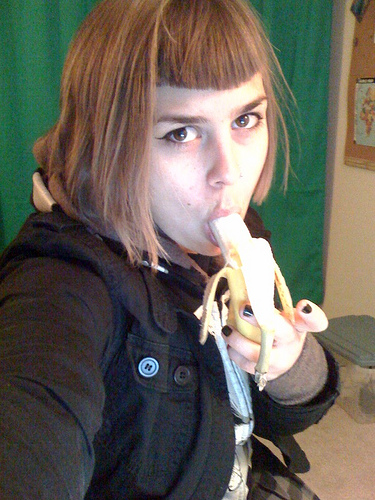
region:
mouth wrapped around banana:
[196, 198, 264, 264]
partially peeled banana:
[211, 225, 291, 375]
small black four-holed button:
[135, 352, 159, 380]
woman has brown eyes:
[158, 108, 272, 147]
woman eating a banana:
[32, 30, 358, 381]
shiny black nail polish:
[296, 300, 317, 320]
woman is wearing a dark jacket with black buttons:
[4, 85, 321, 494]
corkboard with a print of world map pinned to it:
[343, 5, 373, 167]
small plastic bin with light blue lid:
[318, 315, 373, 425]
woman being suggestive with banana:
[23, 4, 333, 297]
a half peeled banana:
[192, 216, 299, 398]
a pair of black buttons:
[134, 356, 196, 385]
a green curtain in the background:
[0, 10, 335, 316]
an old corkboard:
[339, 1, 373, 178]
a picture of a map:
[349, 75, 374, 145]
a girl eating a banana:
[1, 3, 349, 498]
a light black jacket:
[4, 201, 334, 498]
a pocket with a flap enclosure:
[97, 330, 205, 485]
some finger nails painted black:
[219, 297, 315, 355]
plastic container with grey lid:
[304, 307, 374, 422]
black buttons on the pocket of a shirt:
[134, 354, 195, 386]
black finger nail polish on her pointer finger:
[300, 300, 315, 312]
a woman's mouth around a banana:
[196, 189, 260, 250]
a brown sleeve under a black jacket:
[256, 324, 339, 433]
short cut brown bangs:
[123, 7, 293, 109]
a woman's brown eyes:
[154, 98, 269, 154]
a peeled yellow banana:
[197, 205, 300, 388]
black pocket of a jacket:
[93, 314, 209, 499]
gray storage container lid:
[303, 294, 373, 379]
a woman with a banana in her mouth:
[8, 6, 347, 379]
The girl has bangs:
[57, 7, 302, 120]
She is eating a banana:
[178, 200, 309, 359]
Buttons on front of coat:
[127, 346, 196, 410]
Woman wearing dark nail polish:
[301, 300, 323, 316]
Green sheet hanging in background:
[12, 16, 60, 95]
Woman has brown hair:
[50, 48, 171, 233]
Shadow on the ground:
[335, 371, 373, 424]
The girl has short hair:
[48, 35, 169, 264]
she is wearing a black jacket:
[30, 235, 310, 497]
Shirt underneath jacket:
[200, 339, 271, 477]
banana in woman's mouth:
[185, 212, 308, 386]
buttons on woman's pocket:
[132, 340, 204, 396]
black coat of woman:
[8, 187, 337, 498]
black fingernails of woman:
[214, 296, 314, 341]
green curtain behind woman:
[2, 3, 323, 315]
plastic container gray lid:
[321, 307, 374, 422]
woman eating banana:
[4, 6, 325, 499]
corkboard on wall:
[337, 4, 374, 171]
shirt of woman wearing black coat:
[205, 297, 258, 492]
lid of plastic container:
[311, 310, 374, 368]